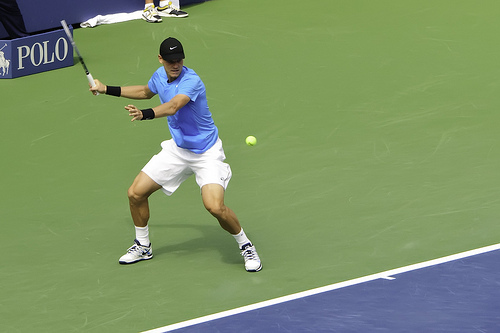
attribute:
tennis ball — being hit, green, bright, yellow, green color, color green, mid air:
[244, 134, 258, 147]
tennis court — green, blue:
[1, 0, 499, 333]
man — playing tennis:
[88, 36, 263, 273]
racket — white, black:
[62, 19, 100, 95]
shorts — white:
[141, 133, 232, 195]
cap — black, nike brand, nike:
[159, 36, 185, 63]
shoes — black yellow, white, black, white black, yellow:
[118, 238, 263, 274]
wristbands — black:
[105, 84, 155, 120]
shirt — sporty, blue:
[146, 65, 218, 156]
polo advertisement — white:
[16, 37, 69, 74]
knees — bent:
[126, 186, 225, 216]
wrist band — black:
[139, 108, 156, 121]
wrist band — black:
[104, 84, 122, 97]